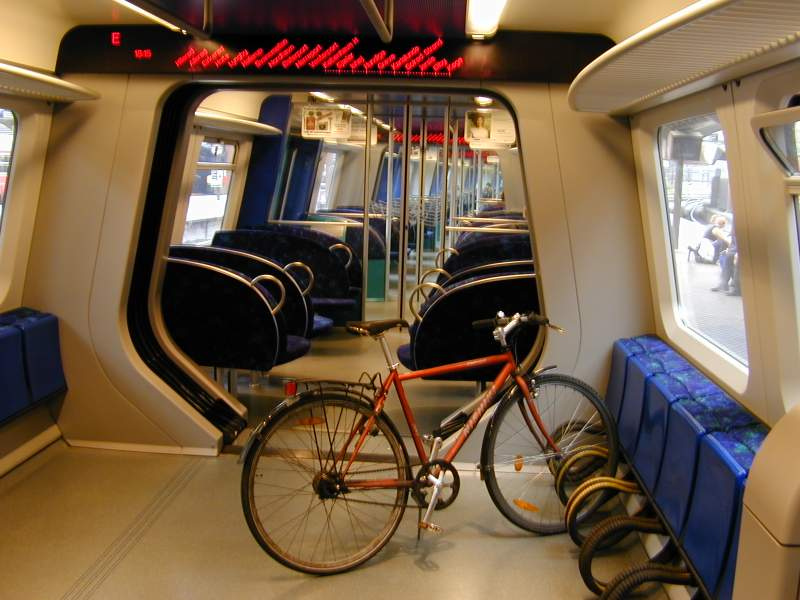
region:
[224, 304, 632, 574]
a two wheeled bicycle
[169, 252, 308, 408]
a chair that you sit in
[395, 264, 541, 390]
a chair that you sit in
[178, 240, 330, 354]
a chair that you sit in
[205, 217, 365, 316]
a chair that you sit in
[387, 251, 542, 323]
a chair that you sit in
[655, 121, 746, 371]
a window on a building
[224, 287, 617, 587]
a bike in a train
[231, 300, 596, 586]
the bike is red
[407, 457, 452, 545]
the pedal is silver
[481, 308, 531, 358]
the handle of a bike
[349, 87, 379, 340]
a silver rode in a bus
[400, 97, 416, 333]
a silver rode in a bus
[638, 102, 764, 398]
the window of a train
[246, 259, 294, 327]
a handle on a board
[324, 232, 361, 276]
a handle on a board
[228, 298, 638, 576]
bike on the train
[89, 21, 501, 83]
red and black design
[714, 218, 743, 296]
person visible through the window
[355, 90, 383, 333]
silver pole on the train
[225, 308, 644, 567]
red and black bike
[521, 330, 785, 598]
blue and black bike rack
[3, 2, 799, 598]
the train looks empty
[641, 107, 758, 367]
window on the wall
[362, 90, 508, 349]
a row of poles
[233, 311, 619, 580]
orange bicycle with black seat and handlebars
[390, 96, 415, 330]
metal pole for passengers to hold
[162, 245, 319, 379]
blue seat for passengers to sit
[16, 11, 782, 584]
inside of a transit train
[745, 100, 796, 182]
partial open window on the train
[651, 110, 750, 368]
window on the side of the train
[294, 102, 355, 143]
commercial sign above a blue seat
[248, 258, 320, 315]
safety handle bars on the blue seat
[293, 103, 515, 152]
three commercial signs hanging inside the train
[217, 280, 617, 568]
bicycle in the train car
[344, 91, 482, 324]
poles in the train car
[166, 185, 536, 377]
seats on the train cars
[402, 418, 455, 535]
pedals on the bicycle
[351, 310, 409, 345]
black seat on the bicycle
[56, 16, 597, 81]
display board above the bicycle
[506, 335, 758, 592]
racks for bicycles on the train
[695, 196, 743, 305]
people on the sidewalk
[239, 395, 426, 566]
back tire on the bicycle